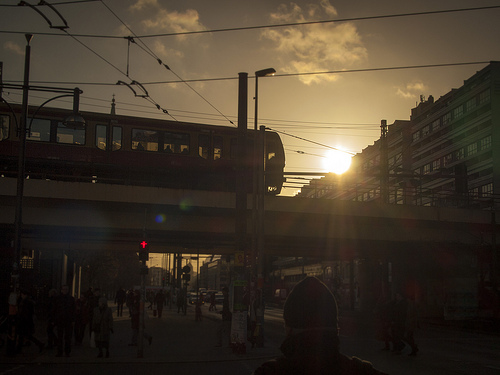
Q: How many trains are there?
A: One.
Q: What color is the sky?
A: Gray.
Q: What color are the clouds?
A: White.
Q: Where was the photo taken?
A: In the city.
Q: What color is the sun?
A: Yellow.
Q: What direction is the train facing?
A: The Right.